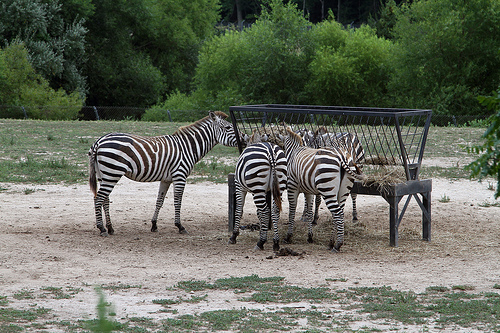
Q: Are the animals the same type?
A: Yes, all the animals are zebras.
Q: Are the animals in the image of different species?
A: No, all the animals are zebras.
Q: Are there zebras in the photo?
A: Yes, there is a zebra.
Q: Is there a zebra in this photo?
A: Yes, there is a zebra.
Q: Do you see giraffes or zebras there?
A: Yes, there is a zebra.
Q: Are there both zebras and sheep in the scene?
A: No, there is a zebra but no sheep.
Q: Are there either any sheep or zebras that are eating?
A: Yes, the zebra is eating.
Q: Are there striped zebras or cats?
A: Yes, there is a striped zebra.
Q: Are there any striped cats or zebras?
A: Yes, there is a striped zebra.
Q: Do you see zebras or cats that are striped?
A: Yes, the zebra is striped.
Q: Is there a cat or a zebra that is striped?
A: Yes, the zebra is striped.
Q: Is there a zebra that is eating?
A: Yes, there is a zebra that is eating.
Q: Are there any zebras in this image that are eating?
A: Yes, there is a zebra that is eating.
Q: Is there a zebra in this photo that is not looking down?
A: Yes, there is a zebra that is eating.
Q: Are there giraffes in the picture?
A: No, there are no giraffes.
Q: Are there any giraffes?
A: No, there are no giraffes.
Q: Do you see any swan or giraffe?
A: No, there are no giraffes or swans.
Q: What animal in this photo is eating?
A: The animal is a zebra.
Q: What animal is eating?
A: The animal is a zebra.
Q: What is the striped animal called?
A: The animal is a zebra.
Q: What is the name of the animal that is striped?
A: The animal is a zebra.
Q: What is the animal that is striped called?
A: The animal is a zebra.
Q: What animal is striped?
A: The animal is a zebra.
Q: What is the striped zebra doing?
A: The zebra is eating.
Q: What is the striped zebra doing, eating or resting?
A: The zebra is eating.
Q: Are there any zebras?
A: Yes, there is a zebra.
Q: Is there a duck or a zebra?
A: Yes, there is a zebra.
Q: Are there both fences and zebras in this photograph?
A: Yes, there are both a zebra and a fence.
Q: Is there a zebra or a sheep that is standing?
A: Yes, the zebra is standing.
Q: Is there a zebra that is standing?
A: Yes, there is a zebra that is standing.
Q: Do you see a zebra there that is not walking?
A: Yes, there is a zebra that is standing .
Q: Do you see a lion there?
A: No, there are no lions.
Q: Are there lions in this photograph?
A: No, there are no lions.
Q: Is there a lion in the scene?
A: No, there are no lions.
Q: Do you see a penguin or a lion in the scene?
A: No, there are no lions or penguins.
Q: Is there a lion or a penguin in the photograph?
A: No, there are no lions or penguins.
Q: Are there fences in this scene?
A: Yes, there is a fence.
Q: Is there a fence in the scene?
A: Yes, there is a fence.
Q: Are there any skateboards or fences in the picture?
A: Yes, there is a fence.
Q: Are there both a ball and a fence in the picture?
A: No, there is a fence but no balls.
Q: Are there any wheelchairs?
A: No, there are no wheelchairs.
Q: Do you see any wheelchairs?
A: No, there are no wheelchairs.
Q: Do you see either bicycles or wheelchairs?
A: No, there are no wheelchairs or bicycles.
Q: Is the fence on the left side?
A: Yes, the fence is on the left of the image.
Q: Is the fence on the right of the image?
A: No, the fence is on the left of the image.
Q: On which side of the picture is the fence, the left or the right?
A: The fence is on the left of the image.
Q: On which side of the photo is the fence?
A: The fence is on the left of the image.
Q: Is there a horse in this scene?
A: No, there are no horses.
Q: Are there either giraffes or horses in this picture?
A: No, there are no horses or giraffes.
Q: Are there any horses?
A: No, there are no horses.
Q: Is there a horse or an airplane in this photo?
A: No, there are no horses or airplanes.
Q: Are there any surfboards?
A: No, there are no surfboards.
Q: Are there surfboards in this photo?
A: No, there are no surfboards.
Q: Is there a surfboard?
A: No, there are no surfboards.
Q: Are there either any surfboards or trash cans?
A: No, there are no surfboards or trash cans.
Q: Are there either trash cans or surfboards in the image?
A: No, there are no surfboards or trash cans.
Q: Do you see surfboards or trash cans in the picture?
A: No, there are no surfboards or trash cans.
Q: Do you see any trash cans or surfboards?
A: No, there are no surfboards or trash cans.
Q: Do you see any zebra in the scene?
A: Yes, there is a zebra.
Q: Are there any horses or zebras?
A: Yes, there is a zebra.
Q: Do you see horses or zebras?
A: Yes, there is a zebra.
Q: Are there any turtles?
A: No, there are no turtles.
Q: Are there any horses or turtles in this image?
A: No, there are no turtles or horses.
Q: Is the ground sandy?
A: Yes, the ground is sandy.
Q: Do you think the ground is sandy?
A: Yes, the ground is sandy.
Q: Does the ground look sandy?
A: Yes, the ground is sandy.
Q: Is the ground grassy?
A: No, the ground is sandy.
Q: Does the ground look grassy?
A: No, the ground is sandy.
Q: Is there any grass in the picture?
A: Yes, there is grass.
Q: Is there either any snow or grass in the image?
A: Yes, there is grass.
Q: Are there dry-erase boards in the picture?
A: No, there are no dry-erase boards.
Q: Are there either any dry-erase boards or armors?
A: No, there are no dry-erase boards or armors.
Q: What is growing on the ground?
A: The grass is growing on the ground.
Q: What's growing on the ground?
A: The grass is growing on the ground.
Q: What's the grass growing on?
A: The grass is growing on the ground.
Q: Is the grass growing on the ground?
A: Yes, the grass is growing on the ground.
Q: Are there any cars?
A: No, there are no cars.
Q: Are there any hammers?
A: No, there are no hammers.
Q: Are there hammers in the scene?
A: No, there are no hammers.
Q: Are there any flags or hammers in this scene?
A: No, there are no hammers or flags.